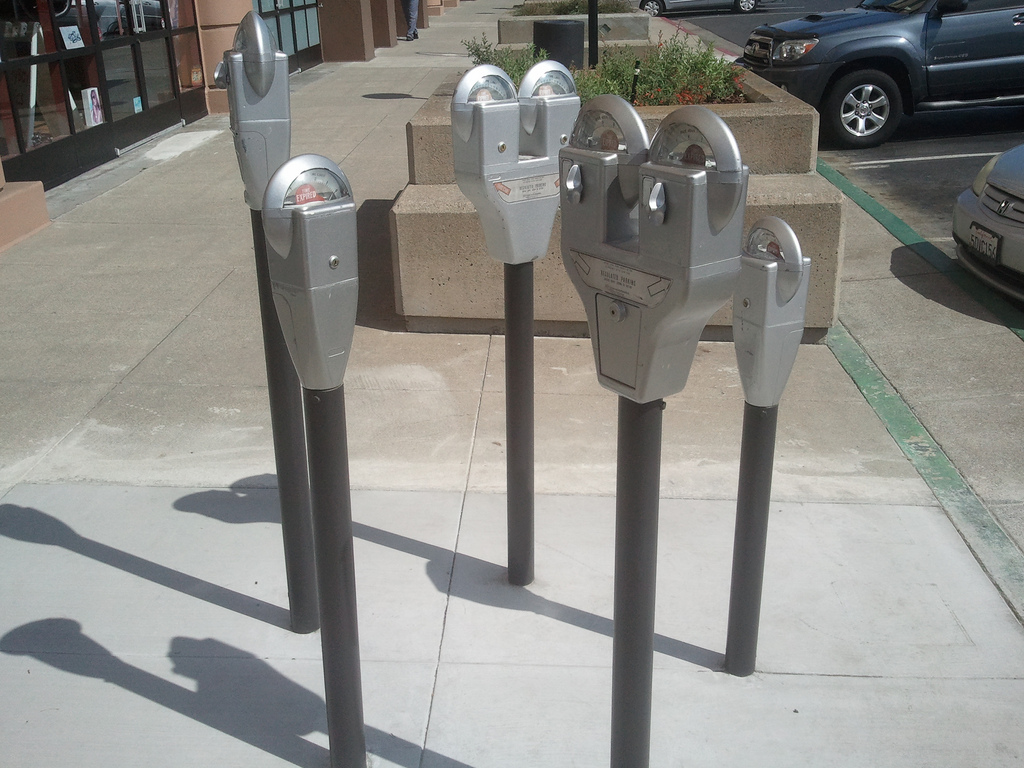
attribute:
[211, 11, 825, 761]
parking meters — collection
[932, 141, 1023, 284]
car — grey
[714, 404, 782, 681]
metal pole — long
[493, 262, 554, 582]
metal pole — long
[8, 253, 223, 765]
sidewalk — Green line 